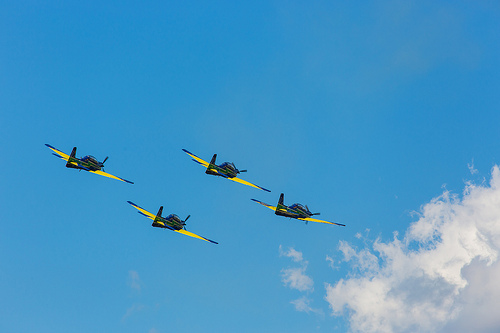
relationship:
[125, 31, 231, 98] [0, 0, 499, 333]
blue sky sky with no clouds blue sky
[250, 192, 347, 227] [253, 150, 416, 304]
plane flying toward cloud flying toward cloud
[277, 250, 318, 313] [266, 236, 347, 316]
clouds drifting away clouds drifting away clouds drifting away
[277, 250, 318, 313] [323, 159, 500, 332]
clouds drifting away gray and white cloud fluffy white cloud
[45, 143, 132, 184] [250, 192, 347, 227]
jets has yellow wing planes with blue plane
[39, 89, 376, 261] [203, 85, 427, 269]
four planes flying flying high above high above the cloud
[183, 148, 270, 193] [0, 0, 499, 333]
jet in blue sky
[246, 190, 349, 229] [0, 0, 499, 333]
plane in blue sky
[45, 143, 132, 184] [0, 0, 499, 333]
jets has yellow wing in blue sky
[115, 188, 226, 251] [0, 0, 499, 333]
plane in blue sky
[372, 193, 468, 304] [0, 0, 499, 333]
fluffy white cloud in blue sky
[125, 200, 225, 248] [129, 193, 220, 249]
wings on plane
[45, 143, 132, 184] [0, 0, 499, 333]
jets has yellow wing flying in blue sky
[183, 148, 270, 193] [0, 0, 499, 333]
jet flying in blue sky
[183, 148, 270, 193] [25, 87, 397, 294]
jet in air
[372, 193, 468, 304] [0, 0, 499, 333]
fluffy white clouds are in blue sky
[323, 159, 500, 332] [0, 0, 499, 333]
fluffy white cloud are in blue sky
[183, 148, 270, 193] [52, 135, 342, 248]
jet has wing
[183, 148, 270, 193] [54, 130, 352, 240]
jet has wing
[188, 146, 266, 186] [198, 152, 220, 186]
jet has tail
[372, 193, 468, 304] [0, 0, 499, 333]
white cloud in sky in blue sky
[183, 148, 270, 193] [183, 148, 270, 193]
jet in jet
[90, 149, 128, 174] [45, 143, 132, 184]
propeller on front in front of jets has yellow wing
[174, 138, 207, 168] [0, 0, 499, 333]
wing upward in blue sky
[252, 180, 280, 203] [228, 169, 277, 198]
tip of wing